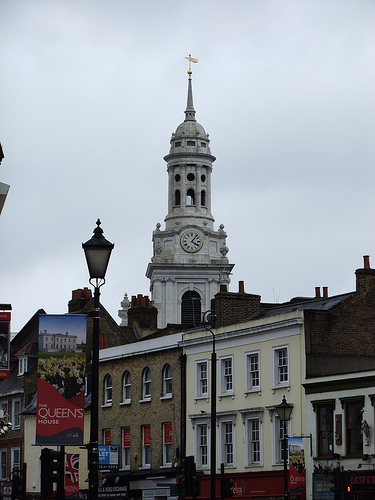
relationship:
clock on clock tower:
[179, 228, 204, 253] [142, 46, 235, 331]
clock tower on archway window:
[145, 54, 234, 329] [179, 289, 204, 327]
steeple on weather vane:
[171, 52, 208, 122] [182, 52, 200, 71]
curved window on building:
[101, 371, 113, 408] [0, 284, 156, 498]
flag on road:
[65, 452, 85, 497] [73, 484, 210, 499]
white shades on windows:
[119, 421, 154, 448] [98, 420, 176, 452]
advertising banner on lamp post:
[37, 311, 92, 444] [82, 218, 114, 498]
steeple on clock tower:
[184, 54, 199, 122] [149, 75, 228, 317]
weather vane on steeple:
[183, 54, 198, 81] [183, 78, 195, 121]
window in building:
[179, 181, 199, 212] [107, 357, 171, 455]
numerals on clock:
[182, 237, 195, 250] [181, 230, 205, 254]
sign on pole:
[37, 314, 87, 447] [55, 439, 65, 495]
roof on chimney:
[328, 249, 374, 328] [333, 252, 373, 296]